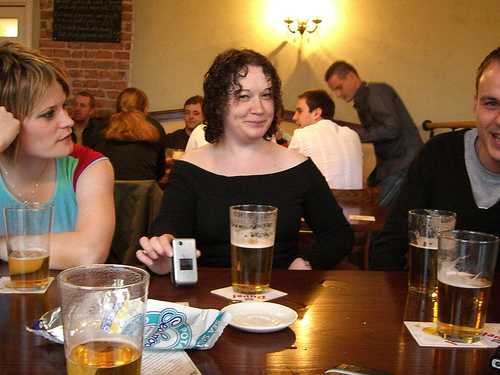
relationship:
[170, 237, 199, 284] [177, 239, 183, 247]
mobile has camera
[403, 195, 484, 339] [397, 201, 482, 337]
series of glasses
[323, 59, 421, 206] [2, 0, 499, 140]
people by wall